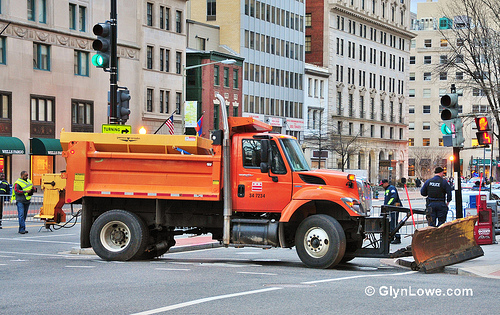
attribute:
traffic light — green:
[91, 17, 129, 124]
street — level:
[4, 152, 498, 309]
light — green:
[88, 17, 131, 108]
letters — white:
[363, 285, 475, 302]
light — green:
[439, 123, 454, 135]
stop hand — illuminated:
[471, 112, 494, 146]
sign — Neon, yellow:
[98, 113, 130, 133]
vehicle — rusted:
[64, 117, 485, 272]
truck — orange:
[58, 105, 381, 273]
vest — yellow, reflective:
[11, 181, 33, 201]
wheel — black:
[289, 210, 346, 267]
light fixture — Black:
[90, 20, 112, 70]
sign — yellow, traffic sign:
[89, 122, 136, 144]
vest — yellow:
[14, 175, 36, 202]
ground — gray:
[6, 227, 479, 307]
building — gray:
[240, 19, 307, 134]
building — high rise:
[325, 0, 417, 180]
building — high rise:
[297, 63, 336, 165]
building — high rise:
[235, 2, 306, 171]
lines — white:
[114, 265, 423, 313]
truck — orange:
[21, 84, 464, 293]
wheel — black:
[294, 213, 363, 269]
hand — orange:
[479, 117, 489, 131]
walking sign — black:
[435, 87, 497, 159]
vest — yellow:
[15, 176, 30, 207]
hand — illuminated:
[473, 113, 489, 149]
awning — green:
[0, 132, 26, 167]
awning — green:
[30, 132, 65, 167]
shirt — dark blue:
[417, 174, 454, 202]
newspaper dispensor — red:
[472, 197, 497, 248]